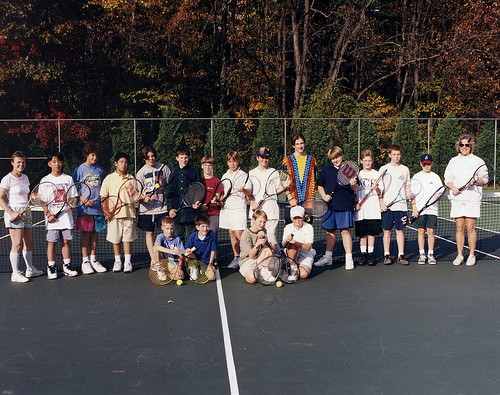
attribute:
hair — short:
[455, 129, 475, 141]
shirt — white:
[450, 156, 482, 191]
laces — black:
[41, 254, 76, 281]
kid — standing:
[3, 149, 37, 282]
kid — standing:
[42, 152, 78, 276]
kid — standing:
[71, 143, 106, 273]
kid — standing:
[109, 150, 141, 275]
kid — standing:
[137, 143, 167, 265]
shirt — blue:
[316, 163, 358, 213]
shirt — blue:
[165, 167, 202, 222]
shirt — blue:
[194, 176, 224, 213]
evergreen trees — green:
[119, 101, 489, 162]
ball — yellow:
[273, 280, 283, 288]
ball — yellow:
[172, 278, 184, 285]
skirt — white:
[444, 192, 481, 218]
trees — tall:
[2, 3, 498, 189]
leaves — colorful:
[447, 50, 492, 92]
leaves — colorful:
[159, 4, 204, 40]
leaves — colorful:
[7, 49, 70, 89]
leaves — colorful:
[471, 7, 493, 30]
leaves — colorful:
[124, 86, 175, 107]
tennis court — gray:
[0, 191, 498, 392]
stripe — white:
[215, 263, 240, 393]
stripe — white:
[403, 225, 498, 262]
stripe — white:
[438, 215, 499, 235]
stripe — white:
[0, 216, 47, 242]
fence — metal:
[5, 113, 492, 156]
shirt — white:
[413, 168, 443, 212]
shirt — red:
[200, 175, 225, 217]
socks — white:
[8, 248, 34, 269]